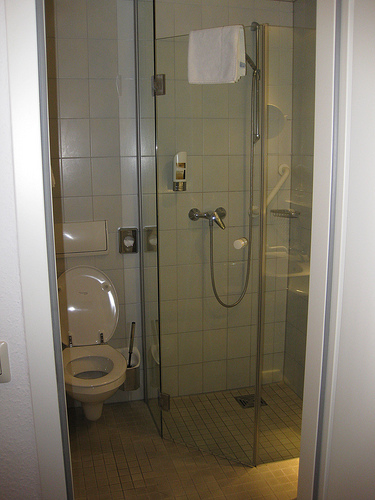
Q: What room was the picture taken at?
A: It was taken at the bathroom.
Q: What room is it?
A: It is a bathroom.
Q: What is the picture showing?
A: It is showing a bathroom.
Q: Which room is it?
A: It is a bathroom.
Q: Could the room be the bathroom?
A: Yes, it is the bathroom.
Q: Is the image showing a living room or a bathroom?
A: It is showing a bathroom.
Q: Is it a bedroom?
A: No, it is a bathroom.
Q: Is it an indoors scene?
A: Yes, it is indoors.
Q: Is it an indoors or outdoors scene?
A: It is indoors.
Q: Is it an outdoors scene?
A: No, it is indoors.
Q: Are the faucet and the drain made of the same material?
A: Yes, both the faucet and the drain are made of metal.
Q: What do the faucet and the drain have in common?
A: The material, both the faucet and the drain are metallic.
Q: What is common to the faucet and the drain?
A: The material, both the faucet and the drain are metallic.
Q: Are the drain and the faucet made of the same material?
A: Yes, both the drain and the faucet are made of metal.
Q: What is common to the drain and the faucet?
A: The material, both the drain and the faucet are metallic.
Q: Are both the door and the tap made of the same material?
A: No, the door is made of glass and the tap is made of metal.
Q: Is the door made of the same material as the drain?
A: No, the door is made of glass and the drain is made of metal.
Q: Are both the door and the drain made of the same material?
A: No, the door is made of glass and the drain is made of metal.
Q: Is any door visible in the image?
A: Yes, there is a door.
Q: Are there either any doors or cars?
A: Yes, there is a door.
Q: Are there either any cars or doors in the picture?
A: Yes, there is a door.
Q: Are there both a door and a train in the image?
A: No, there is a door but no trains.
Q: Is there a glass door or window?
A: Yes, there is a glass door.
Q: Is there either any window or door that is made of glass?
A: Yes, the door is made of glass.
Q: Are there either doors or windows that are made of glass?
A: Yes, the door is made of glass.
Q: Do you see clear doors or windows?
A: Yes, there is a clear door.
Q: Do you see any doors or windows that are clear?
A: Yes, the door is clear.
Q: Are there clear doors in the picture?
A: Yes, there is a clear door.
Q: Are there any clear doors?
A: Yes, there is a clear door.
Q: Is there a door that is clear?
A: Yes, there is a door that is clear.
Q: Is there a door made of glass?
A: Yes, there is a door that is made of glass.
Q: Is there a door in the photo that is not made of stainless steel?
A: Yes, there is a door that is made of glass.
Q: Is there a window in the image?
A: No, there are no windows.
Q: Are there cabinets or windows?
A: No, there are no windows or cabinets.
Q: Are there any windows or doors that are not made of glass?
A: No, there is a door but it is made of glass.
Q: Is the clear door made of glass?
A: Yes, the door is made of glass.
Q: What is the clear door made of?
A: The door is made of glass.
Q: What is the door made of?
A: The door is made of glass.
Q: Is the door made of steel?
A: No, the door is made of glass.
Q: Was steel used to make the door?
A: No, the door is made of glass.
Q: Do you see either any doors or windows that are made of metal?
A: No, there is a door but it is made of glass.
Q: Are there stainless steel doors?
A: No, there is a door but it is made of glass.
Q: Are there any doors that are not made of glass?
A: No, there is a door but it is made of glass.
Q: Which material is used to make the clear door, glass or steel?
A: The door is made of glass.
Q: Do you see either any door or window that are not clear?
A: No, there is a door but it is clear.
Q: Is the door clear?
A: Yes, the door is clear.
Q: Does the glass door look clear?
A: Yes, the door is clear.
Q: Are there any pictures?
A: No, there are no pictures.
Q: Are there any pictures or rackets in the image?
A: No, there are no pictures or rackets.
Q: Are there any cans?
A: No, there are no cans.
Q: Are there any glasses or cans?
A: No, there are no cans or glasses.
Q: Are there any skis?
A: No, there are no skis.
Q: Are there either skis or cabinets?
A: No, there are no skis or cabinets.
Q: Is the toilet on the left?
A: Yes, the toilet is on the left of the image.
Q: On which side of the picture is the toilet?
A: The toilet is on the left of the image.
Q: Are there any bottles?
A: No, there are no bottles.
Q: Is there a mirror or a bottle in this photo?
A: No, there are no bottles or mirrors.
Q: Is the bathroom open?
A: Yes, the bathroom is open.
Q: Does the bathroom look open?
A: Yes, the bathroom is open.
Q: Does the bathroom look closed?
A: No, the bathroom is open.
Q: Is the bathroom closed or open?
A: The bathroom is open.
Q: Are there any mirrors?
A: No, there are no mirrors.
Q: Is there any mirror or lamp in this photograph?
A: No, there are no mirrors or lamps.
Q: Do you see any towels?
A: Yes, there is a towel.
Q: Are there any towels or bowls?
A: Yes, there is a towel.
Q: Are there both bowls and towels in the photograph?
A: Yes, there are both a towel and a bowl.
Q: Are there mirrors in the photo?
A: No, there are no mirrors.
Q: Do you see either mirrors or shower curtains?
A: No, there are no mirrors or shower curtains.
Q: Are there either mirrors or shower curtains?
A: No, there are no mirrors or shower curtains.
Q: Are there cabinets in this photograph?
A: No, there are no cabinets.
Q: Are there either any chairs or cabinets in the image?
A: No, there are no cabinets or chairs.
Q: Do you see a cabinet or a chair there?
A: No, there are no cabinets or chairs.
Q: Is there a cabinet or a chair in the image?
A: No, there are no cabinets or chairs.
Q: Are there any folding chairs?
A: No, there are no folding chairs.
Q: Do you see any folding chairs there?
A: No, there are no folding chairs.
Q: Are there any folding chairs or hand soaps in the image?
A: No, there are no folding chairs or hand soaps.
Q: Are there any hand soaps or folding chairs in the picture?
A: No, there are no folding chairs or hand soaps.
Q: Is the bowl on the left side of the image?
A: Yes, the bowl is on the left of the image.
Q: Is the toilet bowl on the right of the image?
A: No, the bowl is on the left of the image.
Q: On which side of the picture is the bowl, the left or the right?
A: The bowl is on the left of the image.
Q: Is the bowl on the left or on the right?
A: The bowl is on the left of the image.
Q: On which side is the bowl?
A: The bowl is on the left of the image.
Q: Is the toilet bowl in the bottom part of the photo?
A: Yes, the bowl is in the bottom of the image.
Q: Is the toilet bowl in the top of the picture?
A: No, the bowl is in the bottom of the image.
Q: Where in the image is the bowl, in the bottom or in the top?
A: The bowl is in the bottom of the image.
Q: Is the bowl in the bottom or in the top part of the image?
A: The bowl is in the bottom of the image.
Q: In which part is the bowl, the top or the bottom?
A: The bowl is in the bottom of the image.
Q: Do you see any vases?
A: No, there are no vases.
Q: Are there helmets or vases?
A: No, there are no vases or helmets.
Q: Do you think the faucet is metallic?
A: Yes, the faucet is metallic.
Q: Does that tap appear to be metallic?
A: Yes, the tap is metallic.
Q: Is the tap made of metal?
A: Yes, the tap is made of metal.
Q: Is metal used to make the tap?
A: Yes, the tap is made of metal.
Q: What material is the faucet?
A: The faucet is made of metal.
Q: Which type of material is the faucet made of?
A: The faucet is made of metal.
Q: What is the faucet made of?
A: The faucet is made of metal.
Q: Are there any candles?
A: No, there are no candles.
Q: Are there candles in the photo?
A: No, there are no candles.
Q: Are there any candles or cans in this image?
A: No, there are no candles or cans.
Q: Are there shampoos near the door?
A: Yes, there is a shampoo near the door.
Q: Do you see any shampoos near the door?
A: Yes, there is a shampoo near the door.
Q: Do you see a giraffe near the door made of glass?
A: No, there is a shampoo near the door.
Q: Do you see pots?
A: No, there are no pots.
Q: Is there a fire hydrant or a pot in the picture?
A: No, there are no pots or fire hydrants.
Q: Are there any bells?
A: No, there are no bells.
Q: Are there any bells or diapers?
A: No, there are no bells or diapers.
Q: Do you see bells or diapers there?
A: No, there are no bells or diapers.